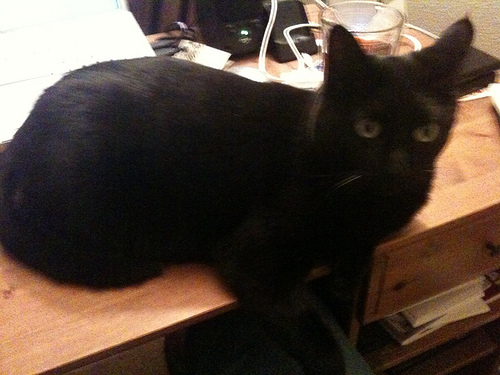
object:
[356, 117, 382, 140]
eye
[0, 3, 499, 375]
desk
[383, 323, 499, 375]
shelving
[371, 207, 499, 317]
drawer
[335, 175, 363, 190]
whiskers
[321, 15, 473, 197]
cat head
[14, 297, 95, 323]
brown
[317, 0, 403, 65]
glass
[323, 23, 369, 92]
ear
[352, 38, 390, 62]
liquid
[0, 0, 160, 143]
laptop screen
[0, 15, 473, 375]
cat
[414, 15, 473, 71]
ear